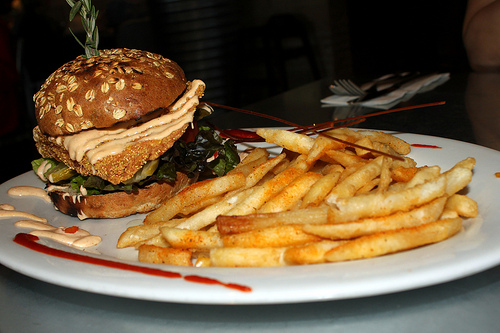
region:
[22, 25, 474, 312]
this is a hamburger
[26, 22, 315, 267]
the burger is at a restaurant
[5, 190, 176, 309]
ketchup and thousand island sauce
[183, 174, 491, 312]
shoe cut french fries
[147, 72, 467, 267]
the french fries are golden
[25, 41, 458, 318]
the plate is white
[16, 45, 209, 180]
the bun has oat seeds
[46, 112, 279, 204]
the meat is breaded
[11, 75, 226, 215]
the burger has greens on it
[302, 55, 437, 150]
fork and knife in distance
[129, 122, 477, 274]
the fries is fresh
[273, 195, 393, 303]
the fries is fresh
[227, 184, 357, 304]
the fries is fresh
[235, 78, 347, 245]
the fries is fresh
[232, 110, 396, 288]
the fries is fresh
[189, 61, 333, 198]
the fries is fresh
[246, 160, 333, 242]
the fries is fresh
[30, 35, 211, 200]
Sandwich on a plate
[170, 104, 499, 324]
Stack of fries on plate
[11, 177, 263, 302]
Sauce design on the plate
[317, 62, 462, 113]
Fork and knife on napkin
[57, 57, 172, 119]
oatmeal on top of bun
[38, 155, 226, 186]
Lettuce and pickles on sandwich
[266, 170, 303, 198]
Seasoning on french fries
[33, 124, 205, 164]
Meat on sandwich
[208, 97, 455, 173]
Decorative accents on plate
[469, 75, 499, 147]
Reflection on the table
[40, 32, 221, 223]
large burger on plate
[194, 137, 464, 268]
french fries on a plate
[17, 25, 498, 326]
plate full of french fries and burger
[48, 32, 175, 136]
hamburger bun on top of meat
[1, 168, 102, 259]
mayonaise drizzled on plate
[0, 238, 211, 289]
long line of ketchup on plate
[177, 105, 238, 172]
lettuce on hamburger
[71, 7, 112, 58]
vegetable sticking out of hamburger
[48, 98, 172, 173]
meat inside hamburger with dressing on top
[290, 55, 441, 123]
silverware in background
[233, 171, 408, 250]
seasoned french fries on the plate.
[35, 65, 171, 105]
oak wheat bun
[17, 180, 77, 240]
thousand island on plate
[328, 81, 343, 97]
spoon on napkin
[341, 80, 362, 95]
fork on napkin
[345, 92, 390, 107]
the knife is on the napkin.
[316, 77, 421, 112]
the silverware is on the table.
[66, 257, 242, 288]
ketchup is on the plate.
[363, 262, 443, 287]
the plate is white.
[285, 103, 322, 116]
the plate is on a brown table.